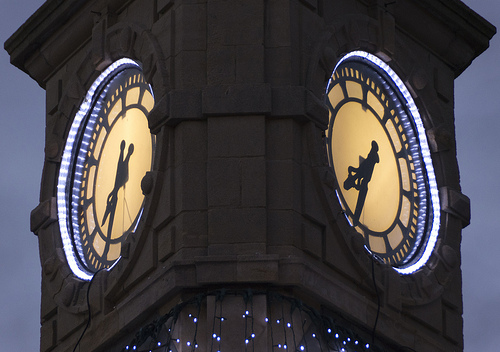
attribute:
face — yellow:
[336, 100, 405, 229]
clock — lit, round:
[306, 44, 454, 283]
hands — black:
[339, 139, 386, 228]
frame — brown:
[295, 25, 466, 325]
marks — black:
[333, 75, 387, 109]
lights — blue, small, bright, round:
[123, 307, 376, 351]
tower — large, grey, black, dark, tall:
[0, 0, 495, 350]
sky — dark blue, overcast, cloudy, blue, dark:
[461, 115, 499, 259]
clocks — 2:
[53, 49, 445, 283]